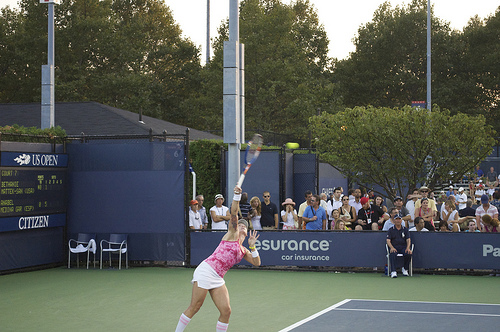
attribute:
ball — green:
[284, 140, 301, 150]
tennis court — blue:
[277, 295, 497, 328]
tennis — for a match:
[177, 139, 291, 329]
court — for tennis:
[262, 274, 498, 328]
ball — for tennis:
[282, 140, 297, 150]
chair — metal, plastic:
[98, 230, 131, 273]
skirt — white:
[188, 257, 226, 290]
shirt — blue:
[299, 207, 329, 234]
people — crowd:
[278, 183, 475, 239]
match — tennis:
[12, 131, 470, 324]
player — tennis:
[181, 131, 267, 329]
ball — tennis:
[284, 139, 298, 149]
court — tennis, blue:
[276, 287, 497, 327]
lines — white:
[333, 280, 383, 319]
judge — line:
[385, 216, 415, 265]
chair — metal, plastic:
[64, 227, 97, 273]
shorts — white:
[190, 255, 228, 291]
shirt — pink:
[209, 230, 242, 277]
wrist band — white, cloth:
[249, 248, 261, 260]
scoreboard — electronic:
[0, 145, 62, 232]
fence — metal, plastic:
[202, 228, 498, 278]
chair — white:
[66, 230, 98, 270]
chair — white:
[97, 230, 131, 269]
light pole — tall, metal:
[220, 0, 247, 214]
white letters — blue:
[250, 236, 499, 256]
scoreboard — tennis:
[0, 164, 68, 214]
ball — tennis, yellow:
[285, 141, 299, 151]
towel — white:
[72, 243, 85, 253]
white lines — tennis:
[274, 295, 497, 327]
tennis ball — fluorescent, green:
[285, 140, 296, 150]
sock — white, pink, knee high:
[175, 310, 193, 330]